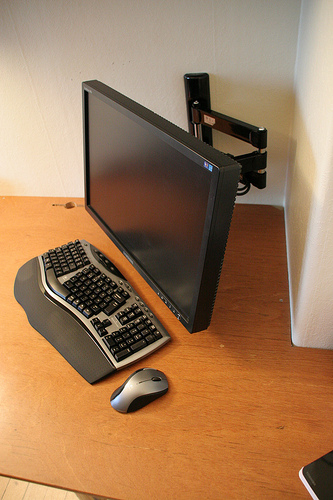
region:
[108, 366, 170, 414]
black and silver computer mouse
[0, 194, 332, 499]
stained desk top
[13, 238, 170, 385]
black and silver keyboard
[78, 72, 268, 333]
black computer monitor mounted on wall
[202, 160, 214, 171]
windows logo on top of monitor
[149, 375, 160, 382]
black wheel on mouse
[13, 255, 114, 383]
black arm rest on keyboard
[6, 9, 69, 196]
crack in tan wall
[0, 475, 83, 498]
wood floor under desk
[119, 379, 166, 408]
this is a mouse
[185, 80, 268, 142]
this is a computer stand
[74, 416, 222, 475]
this is a table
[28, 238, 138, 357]
this is a keybord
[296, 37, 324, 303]
this is a wall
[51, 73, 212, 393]
this is a computer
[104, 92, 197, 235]
this is a monitor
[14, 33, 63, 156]
this is a wall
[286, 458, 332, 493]
this is a computer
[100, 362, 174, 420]
a wireless mouse of computer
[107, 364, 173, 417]
mouse is black and gray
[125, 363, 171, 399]
mouse has a wheel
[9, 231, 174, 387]
a keyboard of computer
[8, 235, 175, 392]
keys are color black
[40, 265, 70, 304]
space bar of keyboard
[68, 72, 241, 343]
the screen of a computer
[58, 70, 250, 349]
screen is turn off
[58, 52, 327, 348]
screen is above the desk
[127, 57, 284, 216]
screen is fixed in the wall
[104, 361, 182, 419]
A computer mouse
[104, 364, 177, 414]
A black and silver tone computer mouse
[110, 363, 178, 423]
A black and silver mouse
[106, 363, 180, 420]
A black and silver mouse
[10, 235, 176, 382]
An ergonomic keyboard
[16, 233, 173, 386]
A black and silver ergonomic keyboard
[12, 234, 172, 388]
A keyboard with wrist rest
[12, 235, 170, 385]
An ergonomic keyboard with wrist rest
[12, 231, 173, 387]
A black and silver tone keyboard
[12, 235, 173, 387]
A black and silvertone ergonomic keyboard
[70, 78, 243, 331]
a black computer screen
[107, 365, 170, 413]
a black and gray mouse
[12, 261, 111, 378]
a wrist protection for the keyboard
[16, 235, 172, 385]
a full computer keyboard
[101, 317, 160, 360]
a number pad on the keyboard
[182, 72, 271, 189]
the screen is mounted to the wall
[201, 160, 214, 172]
small stickers on the screen frame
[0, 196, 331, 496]
a wooden desktop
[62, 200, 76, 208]
a power cord hole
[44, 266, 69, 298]
the space bar is black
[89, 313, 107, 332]
keys on a keyboard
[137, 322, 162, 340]
keys on a keyboard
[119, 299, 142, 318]
keys on a keyboard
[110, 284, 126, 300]
keys on a keyboard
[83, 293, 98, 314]
keys on a keyboard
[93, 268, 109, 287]
keys on a keyboard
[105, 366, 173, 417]
mouse on a desk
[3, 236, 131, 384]
keyboard on a desk